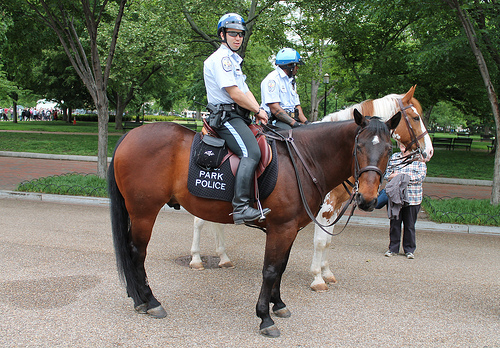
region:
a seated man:
[200, 10, 270, 220]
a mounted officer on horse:
[101, 10, 402, 340]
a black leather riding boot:
[229, 158, 270, 227]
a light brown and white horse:
[186, 84, 437, 293]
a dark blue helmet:
[215, 11, 247, 32]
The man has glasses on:
[220, 26, 249, 44]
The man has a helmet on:
[213, 8, 247, 53]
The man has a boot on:
[231, 195, 271, 229]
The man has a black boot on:
[227, 195, 272, 231]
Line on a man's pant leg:
[224, 122, 249, 160]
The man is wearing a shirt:
[199, 45, 254, 106]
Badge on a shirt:
[217, 59, 233, 73]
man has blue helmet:
[204, 9, 254, 44]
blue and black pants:
[222, 100, 268, 228]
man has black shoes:
[195, 204, 264, 266]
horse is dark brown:
[94, 104, 404, 282]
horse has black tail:
[111, 116, 143, 294]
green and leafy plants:
[49, 156, 119, 216]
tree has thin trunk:
[79, 45, 141, 183]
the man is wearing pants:
[228, 126, 250, 148]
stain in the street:
[15, 278, 96, 313]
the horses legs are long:
[310, 226, 336, 288]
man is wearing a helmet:
[276, 48, 297, 61]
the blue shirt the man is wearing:
[206, 67, 223, 92]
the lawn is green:
[443, 150, 483, 172]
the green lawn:
[439, 148, 469, 172]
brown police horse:
[98, 108, 407, 343]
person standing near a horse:
[376, 130, 426, 263]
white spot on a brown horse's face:
[371, 132, 382, 148]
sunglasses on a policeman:
[224, 29, 244, 41]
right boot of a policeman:
[227, 149, 275, 227]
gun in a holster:
[206, 100, 225, 126]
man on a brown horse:
[202, 13, 274, 225]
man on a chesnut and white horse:
[258, 44, 313, 136]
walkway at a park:
[0, 192, 498, 347]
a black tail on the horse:
[109, 225, 136, 270]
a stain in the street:
[6, 281, 82, 308]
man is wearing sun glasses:
[228, 30, 243, 37]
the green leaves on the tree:
[426, 45, 471, 82]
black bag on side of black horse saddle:
[191, 130, 229, 171]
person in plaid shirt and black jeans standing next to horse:
[381, 138, 429, 261]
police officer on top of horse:
[97, 8, 407, 346]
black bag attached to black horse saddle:
[190, 128, 232, 171]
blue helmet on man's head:
[211, 8, 251, 38]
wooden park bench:
[426, 130, 478, 157]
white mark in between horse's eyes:
[367, 129, 382, 149]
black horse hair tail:
[97, 151, 152, 314]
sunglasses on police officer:
[221, 25, 246, 42]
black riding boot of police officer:
[224, 150, 275, 230]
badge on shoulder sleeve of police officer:
[218, 51, 235, 77]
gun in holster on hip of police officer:
[199, 99, 227, 130]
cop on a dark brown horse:
[198, 11, 273, 225]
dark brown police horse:
[98, 106, 405, 341]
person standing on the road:
[383, 134, 427, 263]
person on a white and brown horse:
[258, 42, 308, 130]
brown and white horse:
[173, 80, 435, 296]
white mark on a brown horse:
[371, 132, 379, 147]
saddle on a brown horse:
[188, 126, 280, 211]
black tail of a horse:
[103, 140, 145, 307]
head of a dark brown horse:
[346, 106, 405, 216]